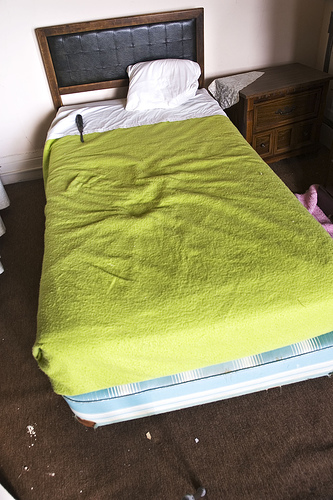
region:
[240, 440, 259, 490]
the floor is brown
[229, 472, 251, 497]
the floor is brown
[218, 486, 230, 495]
the floor is brown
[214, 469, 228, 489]
the floor is brown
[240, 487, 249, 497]
the floor is brown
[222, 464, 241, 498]
the floor is brown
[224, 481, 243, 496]
the floor is brown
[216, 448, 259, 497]
the floor is brown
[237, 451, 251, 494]
the floor is brown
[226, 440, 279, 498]
the floor is brown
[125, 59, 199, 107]
the pillow on the bed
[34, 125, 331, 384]
the green blanket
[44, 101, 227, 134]
the white sheet under the green blanket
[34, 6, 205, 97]
the black and brown head board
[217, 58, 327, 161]
the night table near the bed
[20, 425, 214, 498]
the white debris on the ground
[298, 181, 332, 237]
the pink item on the ground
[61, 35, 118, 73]
the black part of the head board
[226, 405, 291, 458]
the brown carpet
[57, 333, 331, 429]
blue and white striped box spring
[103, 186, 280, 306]
the comforter is green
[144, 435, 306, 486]
the carpet is brown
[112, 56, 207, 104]
the pillow is white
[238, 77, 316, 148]
the cabinet is made of wood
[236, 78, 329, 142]
the cabinet is brown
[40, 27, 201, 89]
the headboard has a black cushion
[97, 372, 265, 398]
the matress is blue and white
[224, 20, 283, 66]
the wall is orange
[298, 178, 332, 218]
the pink clothing is on the floor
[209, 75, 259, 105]
white clothing is on the desk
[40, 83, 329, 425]
a twin bed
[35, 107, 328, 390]
a lime green bed spread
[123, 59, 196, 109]
a white bed pillow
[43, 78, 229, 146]
a white bed sheet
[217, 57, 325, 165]
a bedside table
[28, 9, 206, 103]
a padded head board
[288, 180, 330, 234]
a pink crumpled towl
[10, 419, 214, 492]
white dirty spots on carpet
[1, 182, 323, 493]
a dark brown carpet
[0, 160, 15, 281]
bottom of white curtains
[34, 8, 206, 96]
the wooden framed head board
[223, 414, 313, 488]
the brown carpet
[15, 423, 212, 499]
the debris on the carpet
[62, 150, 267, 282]
the green blanket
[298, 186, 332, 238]
the pink item next to the bed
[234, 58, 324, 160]
the wooden night stand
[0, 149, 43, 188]
the base molding